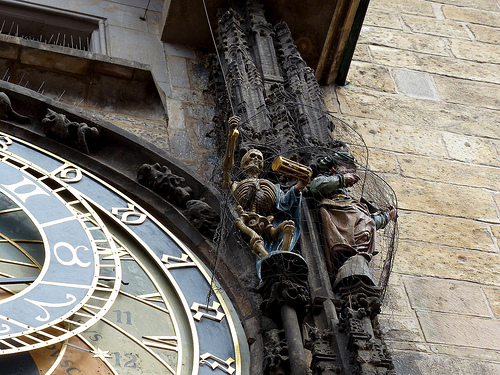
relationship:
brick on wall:
[402, 273, 492, 320] [0, 0, 499, 373]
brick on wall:
[414, 307, 499, 351] [0, 0, 499, 373]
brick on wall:
[387, 272, 406, 307] [0, 0, 499, 373]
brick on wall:
[388, 307, 424, 342] [0, 0, 499, 373]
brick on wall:
[392, 340, 497, 372] [0, 0, 499, 373]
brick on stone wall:
[381, 171, 498, 223] [328, 0, 498, 374]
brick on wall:
[389, 63, 441, 101] [77, 2, 187, 83]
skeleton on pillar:
[219, 125, 317, 269] [204, 10, 393, 372]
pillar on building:
[204, 10, 393, 372] [0, 0, 499, 372]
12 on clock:
[108, 349, 138, 369] [3, 125, 257, 373]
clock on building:
[3, 125, 257, 373] [0, 0, 499, 372]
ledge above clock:
[4, 30, 176, 128] [3, 125, 257, 373]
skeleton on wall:
[219, 115, 313, 269] [0, 0, 499, 373]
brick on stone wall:
[402, 273, 492, 320] [328, 0, 498, 374]